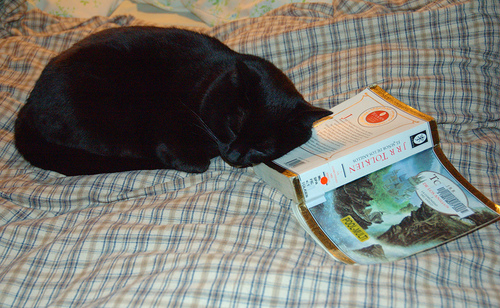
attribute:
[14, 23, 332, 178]
cat — black, lying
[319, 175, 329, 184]
sticker — red, dot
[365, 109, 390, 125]
logo — red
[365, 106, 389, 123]
circle — red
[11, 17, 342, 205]
mammal — small, furry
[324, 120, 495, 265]
cover — outer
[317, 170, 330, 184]
circle — red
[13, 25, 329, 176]
blackcat — black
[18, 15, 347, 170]
cat — large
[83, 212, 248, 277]
blanket — wrinkled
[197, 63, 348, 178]
head — cat's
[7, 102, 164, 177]
tail — curled, under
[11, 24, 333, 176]
feline — domesticated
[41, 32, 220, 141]
fur — black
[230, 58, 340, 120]
ears — pointed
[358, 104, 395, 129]
logo — red, circle, yellow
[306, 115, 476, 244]
book — inverted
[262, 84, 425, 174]
cover book — soft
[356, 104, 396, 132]
circle — white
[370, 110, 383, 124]
type — orange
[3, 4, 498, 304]
sheets — plaid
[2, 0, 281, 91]
light — reflection